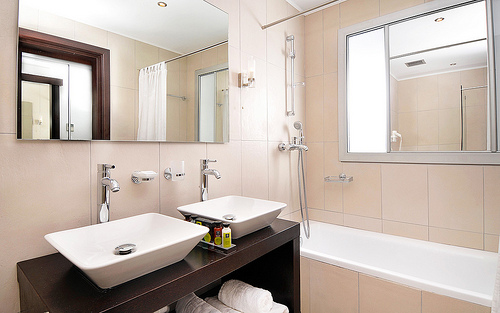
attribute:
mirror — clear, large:
[11, 1, 233, 140]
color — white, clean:
[39, 216, 205, 285]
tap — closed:
[88, 160, 126, 228]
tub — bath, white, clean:
[296, 209, 499, 312]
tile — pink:
[221, 145, 280, 193]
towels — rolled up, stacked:
[206, 288, 290, 313]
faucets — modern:
[93, 155, 220, 209]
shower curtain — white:
[138, 66, 173, 146]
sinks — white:
[32, 178, 311, 294]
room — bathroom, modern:
[5, 4, 498, 309]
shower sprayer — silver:
[289, 119, 318, 171]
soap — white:
[138, 167, 160, 180]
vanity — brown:
[12, 221, 306, 307]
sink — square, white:
[173, 184, 290, 246]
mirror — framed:
[331, 1, 497, 178]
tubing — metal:
[297, 133, 318, 245]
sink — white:
[176, 193, 288, 240]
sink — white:
[44, 210, 210, 289]